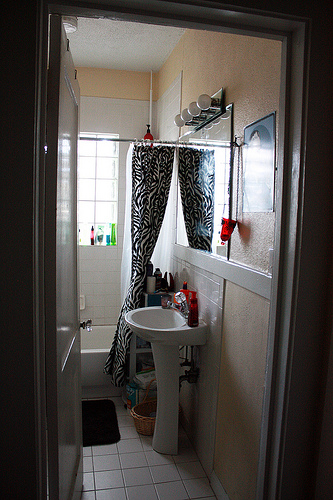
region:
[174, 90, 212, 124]
a row of white light globes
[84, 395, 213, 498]
a white ceramic tile bathroom floor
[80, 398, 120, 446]
a dark brown floor rug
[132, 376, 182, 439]
a brown wicker basket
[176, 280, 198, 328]
red plastic soap bottles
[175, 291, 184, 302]
a clear knob on a faucet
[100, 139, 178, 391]
A black and white shower curtain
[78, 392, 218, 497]
White tiles on the floor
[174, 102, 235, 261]
Mirror hanging on the wall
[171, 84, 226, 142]
Light fixture on the wall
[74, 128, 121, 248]
Daylight coming from a window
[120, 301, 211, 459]
A white porcelain sink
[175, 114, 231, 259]
Reflections in the mirror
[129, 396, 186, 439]
A brown wicker basket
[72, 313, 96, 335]
A doorknob on a door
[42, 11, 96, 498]
A white door is wide open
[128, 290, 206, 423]
a white bathroom sink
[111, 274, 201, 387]
a white sink in the bathroom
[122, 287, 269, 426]
a bathroom sink is white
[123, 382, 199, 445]
a basket in the bathroom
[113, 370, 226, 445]
a brown basket in the bathroom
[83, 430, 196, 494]
white bathroom tile floor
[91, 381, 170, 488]
a black rug on the floor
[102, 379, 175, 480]
a black rug in the bathroom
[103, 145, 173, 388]
the black and white shower curtain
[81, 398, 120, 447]
the dark colored bath mat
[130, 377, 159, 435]
the brown basket with a handle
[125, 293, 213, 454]
the white pedestal sink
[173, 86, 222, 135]
the light fixture with four light bulbs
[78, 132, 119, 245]
the window with sun shining through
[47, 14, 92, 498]
the tall white door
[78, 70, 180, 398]
the tiles on the walls for the bath tub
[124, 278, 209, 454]
the objects on the sink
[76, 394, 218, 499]
the tiles on the floor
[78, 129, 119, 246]
light coming through square panes of window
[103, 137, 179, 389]
Black and white zebra print shower curtain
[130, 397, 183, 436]
Brown wicker basket on floor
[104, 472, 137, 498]
the tile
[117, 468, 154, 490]
the tile is white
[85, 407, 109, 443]
a black rug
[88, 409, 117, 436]
rug on the floor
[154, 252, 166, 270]
linear for the shower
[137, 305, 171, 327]
sink is white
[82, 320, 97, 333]
a door knob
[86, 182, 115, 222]
a window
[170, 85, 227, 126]
bathroom lights are globes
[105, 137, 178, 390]
shower curtain is black and white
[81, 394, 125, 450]
mat on the tiles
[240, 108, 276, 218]
picture on the wall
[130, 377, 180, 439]
basket next to sink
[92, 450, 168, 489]
floor tiles are white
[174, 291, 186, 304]
faucet handle is clear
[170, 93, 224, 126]
four lights above the mirror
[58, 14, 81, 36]
light in the ceiling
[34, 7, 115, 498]
bathroom door is open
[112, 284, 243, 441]
a white sink in the bathroom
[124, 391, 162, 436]
a brown basket on the floor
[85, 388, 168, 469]
a bathroom black rug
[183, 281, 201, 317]
a bottle on the sink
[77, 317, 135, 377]
a white bathroom tub